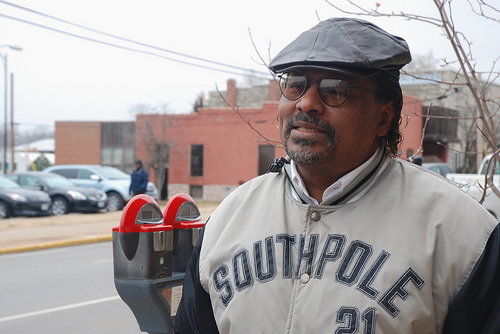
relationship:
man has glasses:
[269, 68, 400, 181] [278, 70, 361, 108]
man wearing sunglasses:
[269, 68, 400, 181] [278, 70, 361, 108]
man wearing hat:
[269, 68, 400, 181] [267, 16, 413, 73]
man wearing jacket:
[269, 68, 400, 181] [196, 164, 499, 326]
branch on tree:
[337, 2, 448, 37] [343, 2, 498, 196]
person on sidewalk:
[121, 156, 156, 203] [5, 193, 232, 255]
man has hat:
[269, 68, 400, 181] [267, 16, 413, 73]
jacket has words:
[196, 164, 499, 326] [203, 228, 429, 319]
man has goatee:
[269, 68, 400, 181] [285, 111, 335, 166]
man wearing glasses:
[269, 68, 400, 181] [278, 70, 361, 108]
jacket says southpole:
[196, 164, 499, 326] [203, 228, 429, 319]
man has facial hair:
[269, 68, 400, 181] [285, 111, 335, 166]